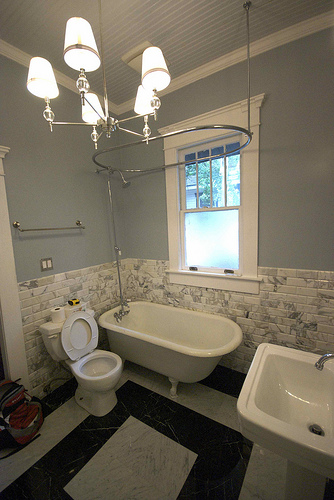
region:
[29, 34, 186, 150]
Five lights are hanging from ceiling.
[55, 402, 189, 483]
Floor is grey and black color.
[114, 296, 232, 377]
One bathtub is in the corner of the room.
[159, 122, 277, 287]
One window is framed in wall.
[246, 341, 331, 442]
Sink is white color.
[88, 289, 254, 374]
Bathtub is white color.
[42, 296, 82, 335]
Tissue roll is on top of flush tank.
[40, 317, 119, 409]
Toilet is white color.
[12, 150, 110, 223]
Wall is green color.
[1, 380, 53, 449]
Back pack is in floor.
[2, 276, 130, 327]
Tiled bathroom wall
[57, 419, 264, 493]
Black and white floor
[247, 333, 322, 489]
White sink in a bathroom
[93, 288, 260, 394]
White bathtub in a bathroom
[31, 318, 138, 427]
White toilet in a bathroom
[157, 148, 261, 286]
Window in a bathroom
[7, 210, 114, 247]
Silver towel rack on a wall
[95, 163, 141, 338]
Silver faucet in a bathroom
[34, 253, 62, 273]
Light switch on a wall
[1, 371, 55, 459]
Bag on the floor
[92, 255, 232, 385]
white bathtub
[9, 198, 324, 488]
bathroom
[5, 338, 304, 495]
black and white square tile pattern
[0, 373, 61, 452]
red backpack on the floor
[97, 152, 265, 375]
window over the bathtub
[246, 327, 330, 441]
white bathroom sink with silver faucet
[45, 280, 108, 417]
toilet paper roll on toilet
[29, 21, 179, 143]
hanging five light chandelier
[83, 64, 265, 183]
curtain holder for a bathtub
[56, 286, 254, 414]
white toilet and bathtub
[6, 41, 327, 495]
a bathroom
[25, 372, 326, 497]
the floor is black and white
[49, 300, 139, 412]
the toilet seat is up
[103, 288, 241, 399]
a claw foot bathtub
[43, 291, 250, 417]
the tub is right next to the toilet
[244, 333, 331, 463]
a white sink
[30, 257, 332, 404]
the wall is tiled part way up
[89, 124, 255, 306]
a metal shower curtain ring hangs above the bathtub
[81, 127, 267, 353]
no curtains are hung around the tub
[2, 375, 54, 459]
a backpack is on the floor by the door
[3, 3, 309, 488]
a large restroom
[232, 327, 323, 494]
a free-standing sink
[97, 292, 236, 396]
an old fashioned style tub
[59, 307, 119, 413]
a toilet with the seat up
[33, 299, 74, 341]
roll of toilet paper on toilet tank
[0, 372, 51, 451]
backpack on the ground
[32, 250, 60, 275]
two switches on the wall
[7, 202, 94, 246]
a towel rack on the wall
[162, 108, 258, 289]
a large, partially frosted window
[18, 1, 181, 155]
a light fixture suspended from above